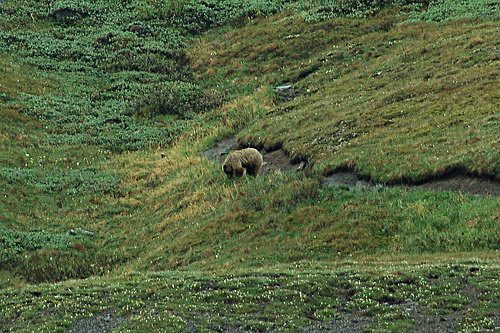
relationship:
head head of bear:
[215, 163, 232, 182] [220, 146, 263, 178]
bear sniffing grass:
[220, 146, 263, 178] [208, 169, 250, 194]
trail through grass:
[211, 134, 484, 196] [1, 2, 484, 327]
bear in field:
[220, 146, 263, 178] [1, 2, 484, 330]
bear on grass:
[220, 146, 263, 178] [1, 2, 484, 327]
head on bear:
[222, 163, 231, 180] [220, 146, 263, 178]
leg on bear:
[243, 167, 263, 179] [221, 142, 265, 180]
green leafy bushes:
[132, 90, 152, 107] [55, 41, 191, 143]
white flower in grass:
[363, 286, 386, 299] [339, 281, 388, 307]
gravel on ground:
[325, 310, 382, 330] [33, 292, 474, 330]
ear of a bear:
[220, 159, 234, 172] [210, 141, 288, 187]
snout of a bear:
[216, 169, 242, 180] [220, 137, 271, 179]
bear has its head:
[220, 146, 263, 178] [215, 158, 236, 180]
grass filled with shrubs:
[80, 73, 136, 128] [104, 73, 498, 128]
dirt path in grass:
[439, 174, 482, 191] [339, 185, 442, 234]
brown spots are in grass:
[221, 27, 275, 59] [219, 14, 437, 154]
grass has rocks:
[0, 0, 500, 333] [398, 308, 463, 329]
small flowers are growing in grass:
[349, 264, 415, 316] [64, 270, 480, 327]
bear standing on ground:
[193, 133, 277, 193] [139, 175, 457, 248]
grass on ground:
[0, 0, 500, 333] [86, 92, 498, 218]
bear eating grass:
[220, 146, 263, 178] [229, 191, 330, 234]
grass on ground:
[0, 0, 500, 333] [42, 100, 480, 256]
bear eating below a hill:
[220, 146, 263, 178] [75, 150, 471, 313]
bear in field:
[220, 146, 263, 178] [99, 17, 479, 287]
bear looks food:
[220, 146, 263, 178] [215, 177, 240, 191]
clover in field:
[21, 143, 81, 173] [10, 1, 208, 244]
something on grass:
[272, 79, 297, 97] [222, 34, 351, 137]